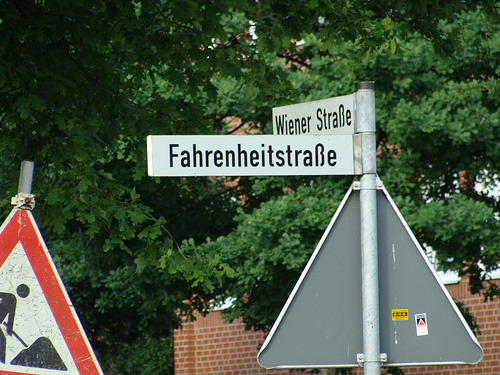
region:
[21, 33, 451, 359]
this picture is outdoors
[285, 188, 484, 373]
this sign is shaped like a triangle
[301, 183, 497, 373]
the sign is gray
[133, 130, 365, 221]
this is a street sign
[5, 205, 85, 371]
this sign is red and white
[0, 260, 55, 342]
this sign has a man on it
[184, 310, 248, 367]
this is a brick wall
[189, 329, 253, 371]
the brick wall is red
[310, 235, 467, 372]
the pole is made of metal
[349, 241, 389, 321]
the pole is light gray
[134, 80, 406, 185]
Two grey street signs.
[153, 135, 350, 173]
The word Fahrenheitstrabe on sign.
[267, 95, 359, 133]
The word Wiener Strabe on sign.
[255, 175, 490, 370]
The back of a sign.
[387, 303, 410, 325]
Yellow sticker on back of sign.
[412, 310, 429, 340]
A red, white and blue sticker.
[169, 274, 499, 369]
A red brick wall.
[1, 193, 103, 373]
Sign outline in red.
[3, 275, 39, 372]
An image representing a person.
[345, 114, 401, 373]
Silver pole holding signs.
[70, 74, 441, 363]
street signs for directions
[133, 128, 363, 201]
this is a name of a street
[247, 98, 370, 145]
this is the name of another street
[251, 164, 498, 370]
this is the back of a sign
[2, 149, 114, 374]
this sign is for shoveling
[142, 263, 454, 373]
a brick wall behind the sign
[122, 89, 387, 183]
the street signs are white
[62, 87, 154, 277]
green leaves on a tree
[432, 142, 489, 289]
a tree on a wall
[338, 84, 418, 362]
a street sign pole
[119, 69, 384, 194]
white and black street signs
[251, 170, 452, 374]
this sign is turned backward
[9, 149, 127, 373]
a red and white sign for workers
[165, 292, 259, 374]
part of a brick house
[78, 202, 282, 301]
leaves in a tree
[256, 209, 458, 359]
the back of the sign is gray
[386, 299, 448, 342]
stickers on the sign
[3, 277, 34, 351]
a character on a sign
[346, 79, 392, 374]
a pole with a sign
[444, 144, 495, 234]
a branch on a tree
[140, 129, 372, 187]
this street sign marks a block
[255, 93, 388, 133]
this sign is the name of a street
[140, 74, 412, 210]
this sign is in a neighborhood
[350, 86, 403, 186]
this part of the sign is metal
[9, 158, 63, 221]
the top of the sign as a metal piece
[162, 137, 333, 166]
the letters on the sign are black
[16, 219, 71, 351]
red and white on the sign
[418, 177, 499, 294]
the window pane on a house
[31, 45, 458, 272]
bushy trees in the neighborhood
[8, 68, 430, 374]
all of these signs are located in a neighborhood